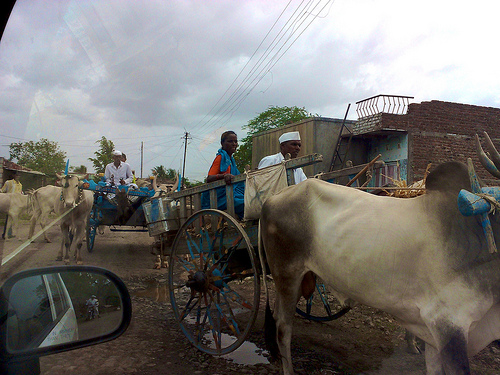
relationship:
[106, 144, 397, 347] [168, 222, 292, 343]
cart has wheel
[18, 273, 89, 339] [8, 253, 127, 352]
vehicle has mirror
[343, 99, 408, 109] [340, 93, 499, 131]
rail on roof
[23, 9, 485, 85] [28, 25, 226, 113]
sky has clouds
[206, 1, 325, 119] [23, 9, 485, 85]
wires in sky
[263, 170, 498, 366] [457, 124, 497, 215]
animal has antlers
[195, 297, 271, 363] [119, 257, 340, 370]
puddle on ground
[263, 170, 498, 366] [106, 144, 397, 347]
animal pulls cart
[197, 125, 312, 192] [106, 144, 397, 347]
people sit in cart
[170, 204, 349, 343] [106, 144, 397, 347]
wheels on cart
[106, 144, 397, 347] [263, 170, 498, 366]
cart pulled by animal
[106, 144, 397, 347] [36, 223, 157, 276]
cart on road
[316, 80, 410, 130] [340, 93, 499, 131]
balcony on roof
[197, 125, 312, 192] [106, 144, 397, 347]
people on cart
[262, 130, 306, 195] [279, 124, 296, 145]
man wears hat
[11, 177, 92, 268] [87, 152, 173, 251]
oxen pulling cart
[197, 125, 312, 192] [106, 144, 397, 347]
people ride in cart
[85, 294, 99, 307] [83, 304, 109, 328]
person on bike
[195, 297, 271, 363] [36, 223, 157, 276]
puddle on road